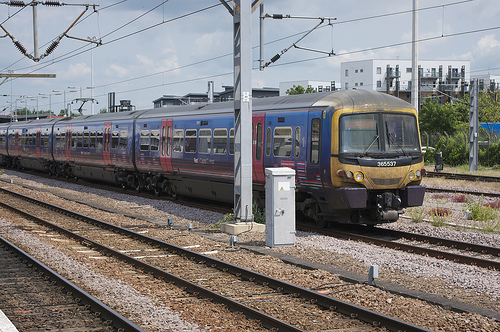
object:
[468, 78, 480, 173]
pole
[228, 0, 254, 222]
pole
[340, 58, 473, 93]
building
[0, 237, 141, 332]
tracks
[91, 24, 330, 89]
power lines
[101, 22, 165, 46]
power lines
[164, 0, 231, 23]
lines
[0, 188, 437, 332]
tracks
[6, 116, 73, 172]
rear wagon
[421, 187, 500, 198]
tracks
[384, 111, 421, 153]
window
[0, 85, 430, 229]
train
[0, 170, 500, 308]
pavement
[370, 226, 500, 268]
set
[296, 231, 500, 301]
set